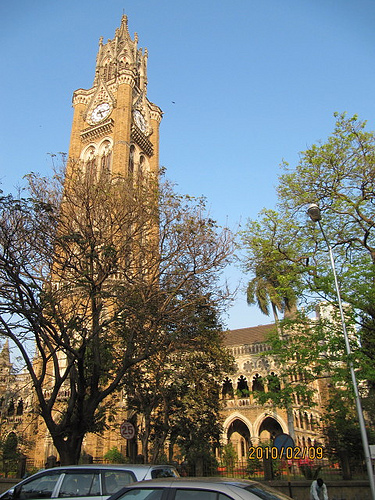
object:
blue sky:
[0, 1, 375, 378]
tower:
[17, 5, 163, 480]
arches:
[221, 414, 252, 460]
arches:
[256, 409, 286, 458]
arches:
[250, 371, 266, 401]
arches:
[265, 368, 281, 396]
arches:
[235, 373, 249, 401]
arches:
[219, 374, 235, 400]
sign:
[271, 431, 296, 459]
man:
[308, 474, 329, 499]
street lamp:
[307, 202, 322, 225]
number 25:
[121, 424, 133, 436]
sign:
[120, 420, 137, 442]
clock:
[84, 100, 112, 128]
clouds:
[0, 1, 375, 374]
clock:
[130, 106, 155, 137]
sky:
[0, 0, 375, 372]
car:
[105, 477, 291, 499]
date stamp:
[244, 440, 325, 464]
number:
[120, 425, 129, 437]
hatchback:
[0, 464, 180, 498]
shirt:
[310, 479, 329, 499]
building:
[0, 7, 372, 484]